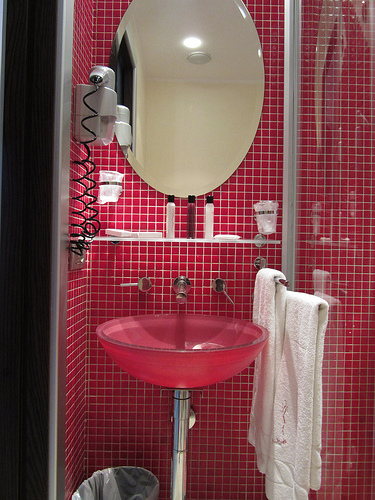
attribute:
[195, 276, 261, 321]
knob — cold water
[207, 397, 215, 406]
tile — red 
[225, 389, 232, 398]
tile — red 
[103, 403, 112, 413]
tile — red , small 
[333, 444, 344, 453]
tile — small , red 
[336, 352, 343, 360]
tile — red , small 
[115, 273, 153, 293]
faucet — silver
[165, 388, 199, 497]
plumbing — silver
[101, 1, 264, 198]
mirror — large , oval 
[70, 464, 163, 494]
can — trash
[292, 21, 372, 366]
shower door — glass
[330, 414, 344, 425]
tile — small, red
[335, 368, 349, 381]
tile — small, red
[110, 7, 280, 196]
mirror — oval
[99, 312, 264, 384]
basin — red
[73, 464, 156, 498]
trash bag — white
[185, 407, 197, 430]
piece — metal, round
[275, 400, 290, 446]
design — red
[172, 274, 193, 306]
faucet — metal, silver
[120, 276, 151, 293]
handle — metal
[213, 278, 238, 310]
handle — metal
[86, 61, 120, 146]
hair dryer — white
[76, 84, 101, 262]
cord — black, spiral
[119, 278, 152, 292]
knob — hot water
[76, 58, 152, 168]
hair drier — white 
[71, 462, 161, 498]
trash can — plastic covered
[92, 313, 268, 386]
sink — red, glass, bowl shaped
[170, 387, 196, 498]
pipe — chrome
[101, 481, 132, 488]
bag — white